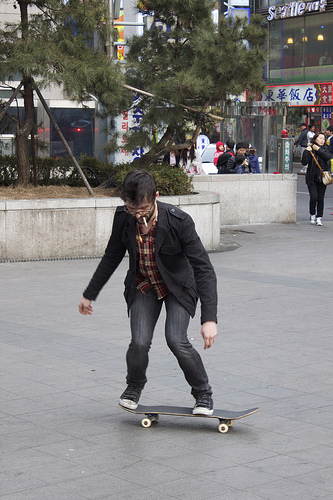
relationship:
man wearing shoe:
[78, 170, 218, 417] [192, 400, 212, 415]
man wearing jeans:
[73, 175, 240, 396] [102, 283, 202, 400]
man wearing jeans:
[78, 170, 218, 417] [124, 284, 209, 391]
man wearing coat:
[78, 170, 218, 417] [71, 198, 226, 323]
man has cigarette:
[78, 170, 218, 417] [142, 217, 147, 226]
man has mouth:
[78, 170, 218, 417] [136, 214, 147, 223]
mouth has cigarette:
[136, 214, 147, 223] [142, 217, 147, 226]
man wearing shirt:
[78, 170, 218, 417] [128, 202, 170, 300]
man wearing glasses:
[78, 170, 218, 417] [121, 201, 155, 213]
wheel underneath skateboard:
[139, 416, 152, 429] [90, 385, 282, 477]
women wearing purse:
[300, 131, 332, 225] [317, 166, 331, 184]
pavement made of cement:
[29, 438, 329, 496] [22, 388, 106, 446]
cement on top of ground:
[22, 388, 106, 446] [258, 425, 322, 489]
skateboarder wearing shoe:
[45, 123, 300, 438] [120, 383, 141, 412]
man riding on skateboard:
[78, 170, 218, 417] [119, 397, 260, 435]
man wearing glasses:
[73, 175, 240, 396] [116, 202, 155, 220]